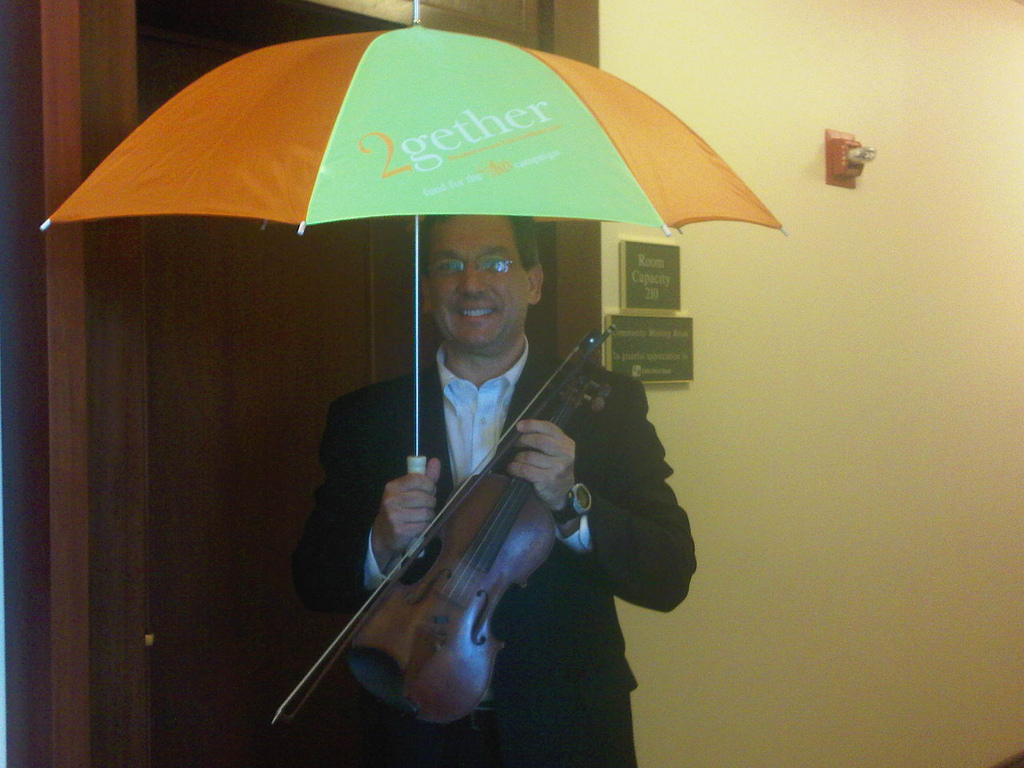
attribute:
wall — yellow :
[596, 0, 1022, 763]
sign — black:
[604, 310, 697, 382]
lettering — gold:
[614, 323, 692, 341]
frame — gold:
[606, 309, 695, 322]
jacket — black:
[295, 357, 699, 761]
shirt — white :
[431, 350, 533, 474]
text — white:
[400, 96, 554, 166]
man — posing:
[268, 206, 703, 758]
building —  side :
[11, 14, 979, 762]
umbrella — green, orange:
[144, 42, 812, 326]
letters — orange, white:
[354, 117, 571, 165]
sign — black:
[622, 236, 739, 342]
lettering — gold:
[619, 238, 684, 332]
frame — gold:
[598, 215, 735, 414]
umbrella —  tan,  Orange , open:
[37, 3, 796, 561]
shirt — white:
[361, 325, 599, 594]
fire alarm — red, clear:
[776, 102, 937, 258]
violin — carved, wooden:
[347, 340, 737, 680]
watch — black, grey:
[519, 448, 636, 559]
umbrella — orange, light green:
[70, 44, 959, 475]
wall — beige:
[526, 16, 1010, 693]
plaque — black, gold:
[591, 281, 758, 387]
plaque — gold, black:
[548, 212, 708, 336]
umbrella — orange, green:
[40, 13, 732, 286]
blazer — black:
[280, 340, 765, 732]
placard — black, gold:
[565, 284, 764, 429]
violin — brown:
[249, 270, 781, 759]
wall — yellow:
[582, 24, 1010, 703]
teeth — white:
[452, 301, 513, 341]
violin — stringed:
[334, 381, 670, 742]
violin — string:
[340, 396, 626, 658]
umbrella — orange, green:
[74, 13, 736, 230]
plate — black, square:
[565, 223, 704, 329]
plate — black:
[565, 301, 732, 418]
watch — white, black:
[537, 465, 646, 569]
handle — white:
[308, 387, 514, 552]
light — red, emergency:
[787, 111, 894, 207]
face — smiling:
[413, 223, 586, 392]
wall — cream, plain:
[703, 273, 987, 755]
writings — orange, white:
[308, 63, 598, 236]